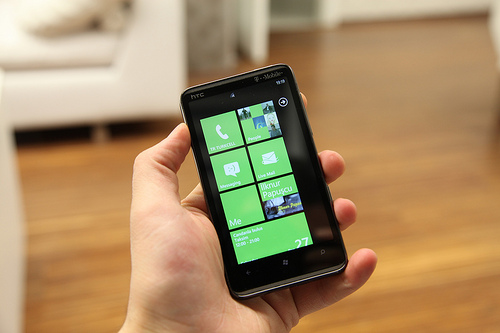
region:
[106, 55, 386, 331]
A person holding up a smart phone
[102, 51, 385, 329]
Caucasian holding rectangular phone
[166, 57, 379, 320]
HTC phone with seven green squares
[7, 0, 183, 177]
white couch on wooden floor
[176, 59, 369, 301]
phone icon on cell phone screen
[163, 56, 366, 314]
male icon on phone screen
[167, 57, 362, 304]
green and white texting logo on phone screen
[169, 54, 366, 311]
Black HTC from T-Mobile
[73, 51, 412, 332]
Caucasian holding phone in left hand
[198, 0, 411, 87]
White door completely open above wooden flooring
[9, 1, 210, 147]
white pillow resting on white couch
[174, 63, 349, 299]
Holding a windows cell phone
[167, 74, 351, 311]
Cell phone is on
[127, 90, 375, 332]
A hand holding cell phone.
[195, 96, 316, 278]
The menu on the phone.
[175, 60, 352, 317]
Windows cell phone.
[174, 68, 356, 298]
The cell phone is on.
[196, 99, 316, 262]
The menu is colored green.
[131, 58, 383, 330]
The cell phone is being used.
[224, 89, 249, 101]
The cell phone has service.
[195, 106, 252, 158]
The phone icon is on the menu.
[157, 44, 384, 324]
a cellphone in hand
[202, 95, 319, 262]
green squares on phone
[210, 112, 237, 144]
a picture of a phone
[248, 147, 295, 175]
an envelope on the phone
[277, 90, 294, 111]
a little white arrow on phone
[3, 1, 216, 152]
a portion of a white couch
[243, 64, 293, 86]
T-mobile in upper right corner of phone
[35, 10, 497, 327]
a light brown hardwood floor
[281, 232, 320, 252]
number 27 on the phone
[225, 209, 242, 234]
Me on the phone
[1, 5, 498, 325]
a scene inside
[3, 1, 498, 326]
a scene during the day time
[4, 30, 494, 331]
a hardwood floor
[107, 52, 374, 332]
a white hand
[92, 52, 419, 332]
a person holding an electronic device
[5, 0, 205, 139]
a white sofa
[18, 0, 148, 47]
a pillow on a sofa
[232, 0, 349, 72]
a door that is open in the background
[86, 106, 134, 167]
a leg of a sofa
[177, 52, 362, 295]
a black smartphone